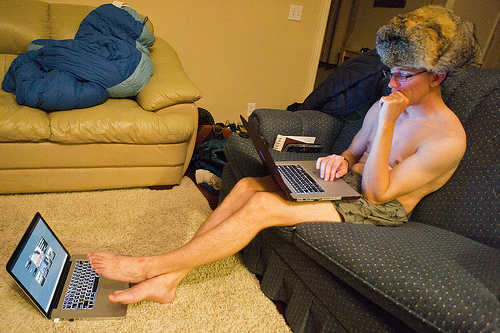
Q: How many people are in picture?
A: One.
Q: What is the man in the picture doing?
A: Working on the computer.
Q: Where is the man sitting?
A: On the couch.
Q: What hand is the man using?
A: Right.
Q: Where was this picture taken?
A: In the living room.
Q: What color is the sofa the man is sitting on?
A: Blue.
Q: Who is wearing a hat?
A: The man in picture.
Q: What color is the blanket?
A: Blue.